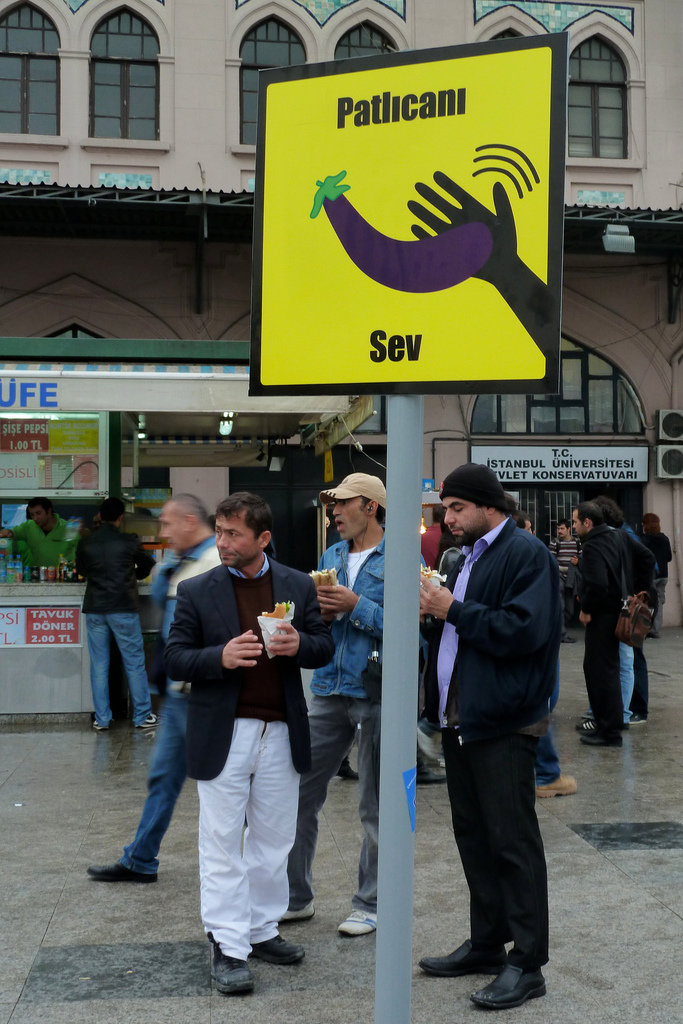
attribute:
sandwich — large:
[259, 599, 288, 617]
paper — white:
[252, 597, 297, 660]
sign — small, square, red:
[25, 602, 80, 643]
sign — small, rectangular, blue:
[402, 763, 417, 835]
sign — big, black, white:
[470, 443, 649, 481]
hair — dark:
[571, 500, 605, 524]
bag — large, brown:
[612, 585, 657, 648]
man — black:
[415, 463, 553, 1009]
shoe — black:
[468, 958, 546, 1010]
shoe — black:
[420, 936, 508, 976]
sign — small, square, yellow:
[47, 416, 98, 453]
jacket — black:
[73, 522, 154, 613]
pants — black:
[561, 576, 577, 626]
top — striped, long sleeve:
[546, 533, 582, 575]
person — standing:
[164, 487, 338, 996]